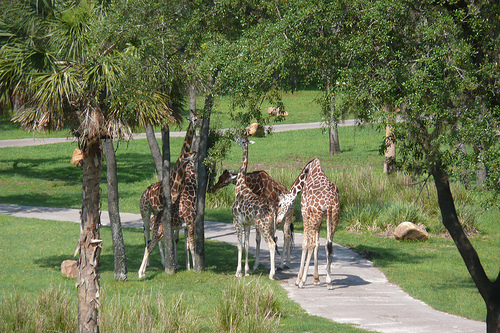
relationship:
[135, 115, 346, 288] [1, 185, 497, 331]
giraffes on sidewalk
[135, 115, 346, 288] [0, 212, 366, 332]
giraffes on grass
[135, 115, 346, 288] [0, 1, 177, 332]
giraffes under tree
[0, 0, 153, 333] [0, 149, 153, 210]
tree cast shadow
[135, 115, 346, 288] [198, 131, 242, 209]
giraffes eat leaves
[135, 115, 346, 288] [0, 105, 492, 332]
giraffes have trail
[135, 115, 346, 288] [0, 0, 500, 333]
giraffes at park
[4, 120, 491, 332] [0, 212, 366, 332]
field has grass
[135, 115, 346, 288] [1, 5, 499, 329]
giraffes in park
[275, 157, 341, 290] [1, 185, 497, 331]
giraffe on sidewalk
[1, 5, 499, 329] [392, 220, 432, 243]
park has rock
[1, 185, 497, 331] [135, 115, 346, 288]
sidewalk with giraffes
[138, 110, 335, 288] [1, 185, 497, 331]
wildlife on sidewalk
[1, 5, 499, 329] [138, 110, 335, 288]
park has wildlife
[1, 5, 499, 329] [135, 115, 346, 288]
park contains giraffes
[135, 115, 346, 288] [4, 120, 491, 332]
giraffes on field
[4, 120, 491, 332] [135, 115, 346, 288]
field with giraffes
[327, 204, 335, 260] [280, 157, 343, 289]
tail on giraffe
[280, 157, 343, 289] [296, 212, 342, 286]
giraffe has legs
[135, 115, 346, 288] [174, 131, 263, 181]
giraffes have necks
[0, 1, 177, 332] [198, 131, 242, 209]
tree have leaves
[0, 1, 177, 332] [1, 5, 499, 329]
tree in park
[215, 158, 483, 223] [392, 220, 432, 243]
bushes behind rock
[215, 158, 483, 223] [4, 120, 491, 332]
bushes in field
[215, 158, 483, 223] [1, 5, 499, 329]
bushes in park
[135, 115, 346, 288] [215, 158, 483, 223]
giraffes near bushes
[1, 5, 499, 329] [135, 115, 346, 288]
park with giraffes